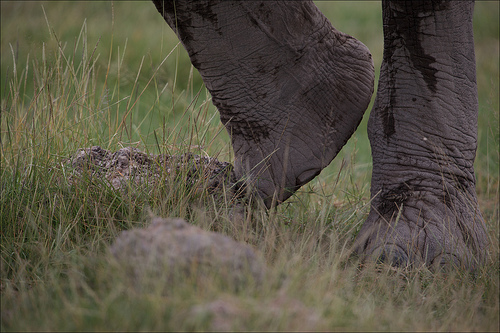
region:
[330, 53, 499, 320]
Elephant foot in the grass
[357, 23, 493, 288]
Elephant foot in the grass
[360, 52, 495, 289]
Elephant foot in the grass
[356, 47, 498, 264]
Elephant foot in the grass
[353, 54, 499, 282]
Elephant foot in the grass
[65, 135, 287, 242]
tip of foot touching rock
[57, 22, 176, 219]
tall blades of grass over a rock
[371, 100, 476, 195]
horizontal wrinkles across foot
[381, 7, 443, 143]
dark marks along leg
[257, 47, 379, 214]
flat sole of foot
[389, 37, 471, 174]
slanted fold along leg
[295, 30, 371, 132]
vertical wrinkles on back of foot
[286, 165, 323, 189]
oval shape on edge of foot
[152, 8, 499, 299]
the feet are grey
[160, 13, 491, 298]
the feet are wrinkled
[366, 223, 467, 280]
toes on the feet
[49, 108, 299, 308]
rocks on the ground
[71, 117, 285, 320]
the rocks are grey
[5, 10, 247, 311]
yellow stringy grass on ground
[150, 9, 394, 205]
the foot is raised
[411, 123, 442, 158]
white spot on leg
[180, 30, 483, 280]
Hooves in the photo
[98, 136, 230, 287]
Rock on the field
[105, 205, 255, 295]
Rock in the field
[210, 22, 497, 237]
Elephant legs in the picture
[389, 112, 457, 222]
Gray skin in the elephant.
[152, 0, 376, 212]
One leg of the elephant is raised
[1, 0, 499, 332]
Grass underneath the elephant's feet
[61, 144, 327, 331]
Dirt mounds amidst the grass field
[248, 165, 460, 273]
Toenails on the elephant's feet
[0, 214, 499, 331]
Out of focus grass and dirt in the foreground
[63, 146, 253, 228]
Dirt mound getting kicked by the elephant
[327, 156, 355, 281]
this is a tall grass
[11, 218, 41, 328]
this is a tall grass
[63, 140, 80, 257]
this is a tall grass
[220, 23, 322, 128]
the feet are large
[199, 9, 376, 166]
the feet are gray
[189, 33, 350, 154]
the skin is rough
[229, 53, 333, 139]
the skin is gray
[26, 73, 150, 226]
the grass is yellow and green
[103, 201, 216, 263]
this is a rock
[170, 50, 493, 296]
The elephant has big feet.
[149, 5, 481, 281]
The elephant's feet are dirty.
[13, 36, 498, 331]
The grass is green underneath the elephant's feet.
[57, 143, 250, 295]
A pile of dirt on the ground by the elephants feet.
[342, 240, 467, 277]
The elephants nails are dirty.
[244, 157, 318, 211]
The elephants nails are dirty.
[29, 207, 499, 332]
The grass is green.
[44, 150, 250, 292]
The dirt is brown.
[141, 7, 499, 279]
The elephant is grey.